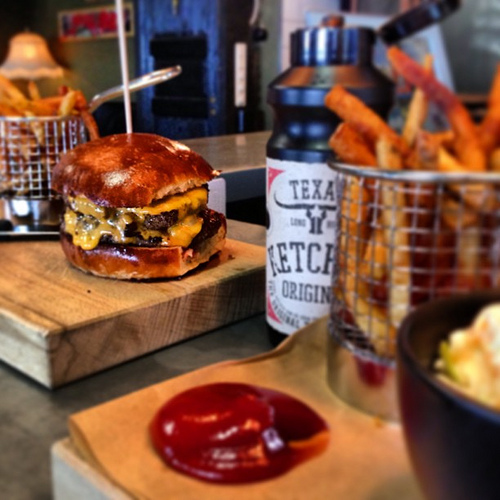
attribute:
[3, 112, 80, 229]
basket — silver ,  metal wire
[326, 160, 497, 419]
container — Metal 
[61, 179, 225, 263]
cheese — yellow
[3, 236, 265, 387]
brown board — wooden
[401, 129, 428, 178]
ground — hanging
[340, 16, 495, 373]
fries — crispy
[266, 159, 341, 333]
whitelabel — white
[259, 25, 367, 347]
bottle — open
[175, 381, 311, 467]
red ketchup —  puddle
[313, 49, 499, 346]
fries — french, long slices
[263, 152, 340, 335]
label — white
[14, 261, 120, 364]
wooden board — wooden , for cutting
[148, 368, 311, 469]
ketchup — red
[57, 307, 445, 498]
bag — brown, paper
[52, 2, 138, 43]
picture — colorful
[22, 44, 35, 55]
light — on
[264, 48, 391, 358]
bottle — ketchup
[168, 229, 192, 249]
cheese — melted